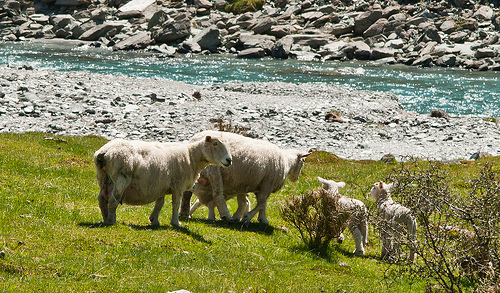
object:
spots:
[118, 173, 132, 183]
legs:
[108, 165, 131, 226]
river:
[0, 34, 498, 125]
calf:
[308, 164, 433, 265]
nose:
[224, 156, 232, 163]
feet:
[93, 194, 183, 232]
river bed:
[1, 65, 499, 160]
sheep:
[359, 175, 426, 269]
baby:
[361, 175, 428, 271]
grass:
[0, 128, 500, 291]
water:
[4, 41, 498, 104]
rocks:
[0, 0, 500, 154]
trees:
[376, 160, 496, 289]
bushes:
[365, 172, 495, 263]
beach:
[82, 68, 317, 131]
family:
[75, 122, 409, 245]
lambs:
[363, 180, 428, 265]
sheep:
[94, 132, 234, 230]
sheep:
[165, 127, 314, 225]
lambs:
[184, 169, 249, 229]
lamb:
[313, 176, 371, 254]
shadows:
[77, 219, 218, 248]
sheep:
[306, 173, 369, 265]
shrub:
[279, 194, 371, 261]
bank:
[0, 0, 499, 145]